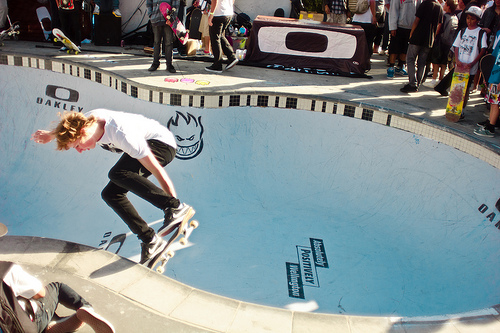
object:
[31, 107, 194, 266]
man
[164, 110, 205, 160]
fireball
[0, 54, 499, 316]
pool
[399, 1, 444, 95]
people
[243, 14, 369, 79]
desk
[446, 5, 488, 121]
boy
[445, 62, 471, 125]
skateboard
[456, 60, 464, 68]
hand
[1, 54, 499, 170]
edge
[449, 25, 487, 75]
t shirt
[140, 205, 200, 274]
skateboard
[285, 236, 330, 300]
writing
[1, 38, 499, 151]
pavement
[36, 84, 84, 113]
logo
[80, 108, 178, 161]
shirt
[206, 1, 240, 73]
person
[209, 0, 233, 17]
shirt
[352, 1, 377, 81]
person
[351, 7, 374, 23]
shirt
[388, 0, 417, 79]
person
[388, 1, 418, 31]
shirt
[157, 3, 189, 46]
skateboard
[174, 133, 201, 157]
face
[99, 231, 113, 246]
logo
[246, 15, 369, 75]
tablecloth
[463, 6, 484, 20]
hat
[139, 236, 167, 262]
shoe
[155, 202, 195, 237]
shoe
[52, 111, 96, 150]
hair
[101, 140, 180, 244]
pants